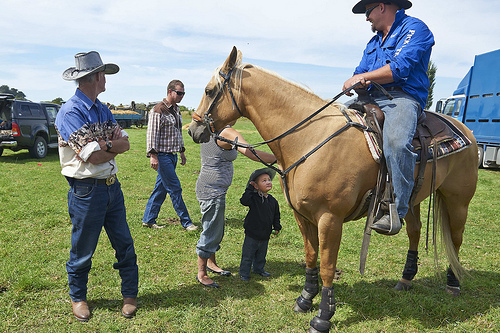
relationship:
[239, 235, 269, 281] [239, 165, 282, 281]
blue jeans on child